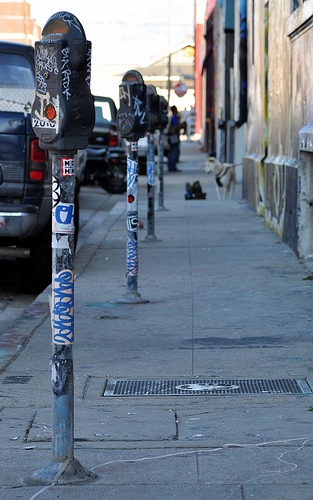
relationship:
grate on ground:
[104, 377, 311, 396] [0, 137, 313, 499]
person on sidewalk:
[167, 103, 188, 174] [169, 202, 231, 299]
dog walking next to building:
[205, 157, 237, 200] [237, 12, 312, 254]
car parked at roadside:
[0, 38, 88, 290] [0, 168, 114, 343]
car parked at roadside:
[85, 95, 127, 184] [0, 168, 114, 343]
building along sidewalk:
[193, 0, 313, 259] [183, 259, 286, 455]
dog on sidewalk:
[205, 156, 235, 201] [137, 139, 249, 278]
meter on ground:
[115, 69, 149, 303] [0, 137, 313, 499]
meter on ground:
[28, 9, 100, 484] [0, 137, 313, 499]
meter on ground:
[142, 84, 162, 243] [0, 137, 313, 499]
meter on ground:
[157, 94, 168, 211] [0, 137, 313, 499]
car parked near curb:
[0, 38, 88, 290] [0, 191, 122, 372]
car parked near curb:
[79, 92, 126, 194] [0, 191, 122, 372]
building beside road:
[247, 3, 312, 228] [83, 188, 105, 214]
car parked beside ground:
[0, 38, 88, 290] [0, 137, 313, 499]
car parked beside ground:
[85, 95, 127, 184] [0, 137, 313, 499]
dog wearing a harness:
[205, 157, 237, 200] [215, 162, 243, 180]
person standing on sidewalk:
[167, 105, 180, 171] [91, 118, 276, 238]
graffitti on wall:
[255, 12, 288, 231] [244, 0, 307, 269]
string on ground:
[28, 426, 311, 498] [1, 114, 311, 498]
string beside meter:
[28, 426, 311, 498] [26, 9, 91, 486]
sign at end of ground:
[171, 81, 185, 95] [0, 137, 313, 499]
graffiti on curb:
[0, 294, 43, 381] [1, 195, 168, 385]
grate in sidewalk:
[99, 375, 311, 396] [96, 94, 297, 319]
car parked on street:
[0, 38, 88, 290] [1, 170, 121, 358]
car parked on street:
[85, 95, 127, 184] [1, 170, 121, 358]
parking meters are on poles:
[30, 10, 95, 153] [22, 154, 98, 483]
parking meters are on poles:
[114, 68, 149, 143] [120, 141, 152, 304]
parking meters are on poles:
[146, 83, 158, 130] [140, 131, 162, 242]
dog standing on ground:
[205, 157, 237, 200] [0, 137, 313, 499]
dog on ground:
[205, 157, 237, 200] [0, 137, 313, 499]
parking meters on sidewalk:
[29, 8, 168, 139] [114, 131, 311, 473]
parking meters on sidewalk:
[114, 68, 149, 143] [114, 131, 311, 473]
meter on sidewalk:
[141, 84, 163, 242] [114, 131, 311, 473]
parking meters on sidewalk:
[157, 94, 168, 208] [114, 131, 311, 473]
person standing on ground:
[167, 105, 180, 171] [0, 137, 313, 499]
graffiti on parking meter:
[62, 46, 73, 101] [28, 4, 146, 401]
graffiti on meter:
[118, 84, 145, 119] [115, 69, 149, 303]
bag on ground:
[98, 161, 126, 192] [0, 137, 313, 499]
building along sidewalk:
[193, 0, 313, 259] [134, 197, 272, 479]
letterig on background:
[61, 158, 74, 174] [62, 158, 65, 172]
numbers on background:
[30, 118, 61, 132] [55, 116, 60, 131]